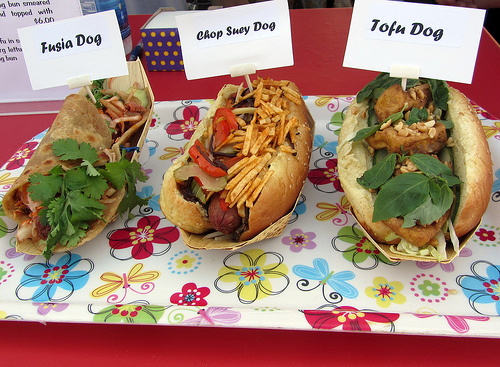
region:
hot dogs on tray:
[1, 2, 499, 357]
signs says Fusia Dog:
[20, 13, 132, 89]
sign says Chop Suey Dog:
[173, 9, 304, 73]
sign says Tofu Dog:
[356, 0, 486, 91]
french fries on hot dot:
[162, 73, 317, 250]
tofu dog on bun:
[343, 68, 498, 279]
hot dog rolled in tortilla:
[20, 88, 140, 265]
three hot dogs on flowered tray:
[1, 90, 498, 342]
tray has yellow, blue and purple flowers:
[0, 90, 496, 350]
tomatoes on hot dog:
[186, 70, 247, 182]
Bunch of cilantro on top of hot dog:
[27, 135, 149, 257]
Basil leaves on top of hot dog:
[356, 153, 464, 226]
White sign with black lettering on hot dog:
[341, 0, 486, 85]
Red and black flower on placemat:
[293, 303, 401, 331]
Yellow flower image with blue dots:
[165, 249, 202, 276]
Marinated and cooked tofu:
[368, 120, 447, 154]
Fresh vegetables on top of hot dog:
[178, 103, 243, 198]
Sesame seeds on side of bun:
[451, 81, 498, 239]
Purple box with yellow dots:
[140, 5, 203, 73]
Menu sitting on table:
[0, 1, 82, 116]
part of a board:
[388, 256, 394, 265]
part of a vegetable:
[416, 176, 427, 195]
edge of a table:
[256, 315, 266, 335]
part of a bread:
[246, 215, 248, 217]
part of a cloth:
[248, 285, 263, 319]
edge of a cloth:
[179, 265, 234, 323]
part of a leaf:
[418, 156, 426, 174]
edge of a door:
[266, 343, 276, 349]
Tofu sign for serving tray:
[343, 1, 490, 85]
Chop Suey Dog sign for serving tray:
[171, 0, 311, 82]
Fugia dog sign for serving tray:
[16, 7, 139, 79]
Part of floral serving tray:
[139, 247, 248, 303]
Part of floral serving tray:
[291, 259, 416, 303]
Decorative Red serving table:
[20, 342, 126, 364]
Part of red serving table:
[158, 335, 254, 365]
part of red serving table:
[290, 344, 364, 362]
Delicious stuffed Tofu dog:
[335, 81, 493, 266]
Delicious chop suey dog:
[156, 77, 313, 250]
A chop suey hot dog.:
[166, 5, 315, 270]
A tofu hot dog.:
[328, 5, 495, 245]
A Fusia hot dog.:
[6, 16, 161, 265]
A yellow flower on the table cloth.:
[211, 248, 295, 303]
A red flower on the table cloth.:
[108, 211, 180, 269]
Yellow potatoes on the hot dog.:
[223, 144, 265, 209]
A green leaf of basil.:
[362, 164, 428, 217]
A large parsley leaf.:
[24, 175, 101, 261]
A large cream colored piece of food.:
[176, 163, 225, 193]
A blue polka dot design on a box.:
[136, 20, 183, 75]